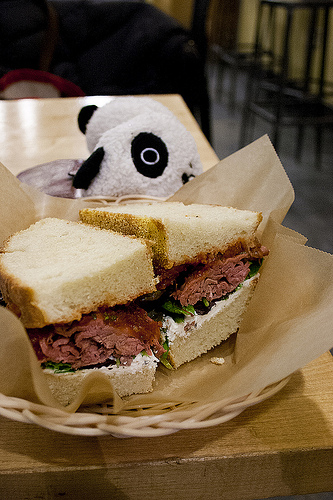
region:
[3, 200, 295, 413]
sandwich that has been cut in half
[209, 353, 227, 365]
bread crumb that broke off the sandwich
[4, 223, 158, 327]
thick piece of bread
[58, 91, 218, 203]
white and black stuffed animal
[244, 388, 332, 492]
shadow on the table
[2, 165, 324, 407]
sandwich sitting on brown paper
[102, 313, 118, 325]
small bits of green on the meat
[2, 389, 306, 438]
edge of the braided basket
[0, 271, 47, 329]
brown crust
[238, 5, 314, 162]
tall black stool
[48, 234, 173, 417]
a sandwich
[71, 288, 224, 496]
a sandwich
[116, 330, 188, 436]
a sandwich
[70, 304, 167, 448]
a sandwich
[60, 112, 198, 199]
black and white stuffed toy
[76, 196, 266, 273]
a slice of bread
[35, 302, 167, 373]
pink meat on the sandwich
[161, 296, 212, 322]
a leaf of green lettuce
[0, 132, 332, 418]
a brown piece of paper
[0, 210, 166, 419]
half of a sandwich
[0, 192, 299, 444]
a brown wicker basket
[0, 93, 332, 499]
a brown wooden table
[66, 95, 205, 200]
a black and white stuffed animal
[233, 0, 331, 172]
a black stool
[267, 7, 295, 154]
the leg of a stool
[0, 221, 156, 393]
The left half of a sandwich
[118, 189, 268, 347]
The right half of a sandwich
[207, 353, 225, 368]
A bread crumb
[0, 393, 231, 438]
A wooden weaved basket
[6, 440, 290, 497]
The edge of a wooden table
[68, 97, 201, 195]
A black and white stuffed animal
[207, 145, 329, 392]
Brown paper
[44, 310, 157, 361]
Meat inside of a sandwich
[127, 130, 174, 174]
The eye of a stuffed animal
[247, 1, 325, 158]
A tall black chair